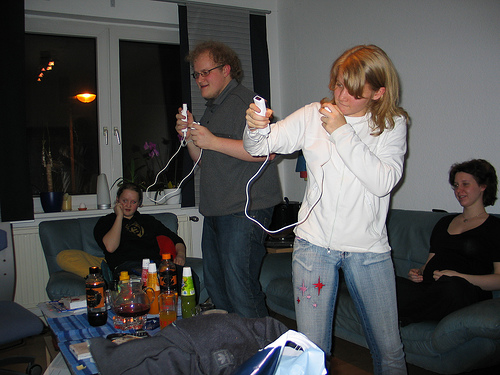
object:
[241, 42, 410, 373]
woman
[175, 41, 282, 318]
man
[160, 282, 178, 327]
bottles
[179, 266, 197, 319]
bottle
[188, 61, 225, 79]
glasses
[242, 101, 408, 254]
shirt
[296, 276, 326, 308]
design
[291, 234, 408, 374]
jeans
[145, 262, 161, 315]
bottle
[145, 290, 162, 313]
orange liquid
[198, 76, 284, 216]
shirt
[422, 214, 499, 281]
top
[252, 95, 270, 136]
wiimote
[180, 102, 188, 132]
wiimote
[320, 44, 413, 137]
blonde hair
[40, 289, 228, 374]
coffee table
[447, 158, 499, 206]
hair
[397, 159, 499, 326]
lady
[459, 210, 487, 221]
necklace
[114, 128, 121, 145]
handles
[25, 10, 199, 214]
window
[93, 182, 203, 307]
girl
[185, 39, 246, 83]
hair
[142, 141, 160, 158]
orchid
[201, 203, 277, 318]
jeans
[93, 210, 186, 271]
shirt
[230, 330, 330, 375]
plastic bag